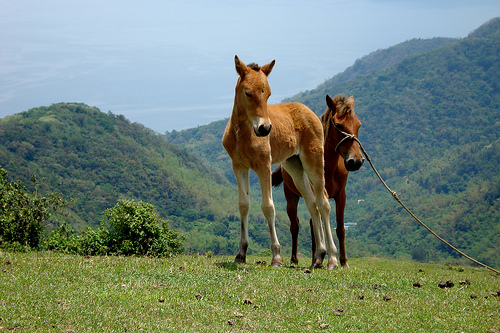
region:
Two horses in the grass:
[225, 53, 360, 270]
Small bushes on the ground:
[3, 169, 187, 254]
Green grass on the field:
[6, 246, 496, 331]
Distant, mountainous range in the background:
[20, 18, 496, 233]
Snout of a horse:
[250, 103, 274, 135]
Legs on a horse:
[224, 157, 340, 279]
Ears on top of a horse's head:
[235, 55, 274, 75]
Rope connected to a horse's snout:
[337, 125, 496, 277]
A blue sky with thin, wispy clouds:
[4, 3, 499, 113]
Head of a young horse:
[232, 53, 276, 137]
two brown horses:
[218, 52, 366, 272]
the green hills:
[3, 12, 498, 256]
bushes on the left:
[0, 159, 185, 261]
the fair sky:
[2, 2, 499, 132]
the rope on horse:
[337, 132, 494, 274]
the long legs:
[233, 157, 353, 272]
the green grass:
[4, 247, 499, 332]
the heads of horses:
[229, 44, 364, 171]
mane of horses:
[243, 59, 350, 116]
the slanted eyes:
[236, 87, 364, 132]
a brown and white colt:
[206, 65, 336, 267]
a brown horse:
[314, 85, 371, 242]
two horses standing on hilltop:
[194, 23, 389, 296]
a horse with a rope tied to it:
[319, 94, 479, 305]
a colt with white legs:
[227, 158, 319, 277]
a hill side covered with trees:
[373, 35, 488, 201]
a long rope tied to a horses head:
[339, 123, 497, 282]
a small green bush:
[60, 201, 202, 273]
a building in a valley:
[337, 210, 359, 245]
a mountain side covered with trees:
[0, 105, 179, 200]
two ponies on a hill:
[179, 38, 407, 295]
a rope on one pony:
[335, 129, 499, 284]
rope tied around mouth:
[328, 127, 390, 205]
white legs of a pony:
[221, 160, 390, 272]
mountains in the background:
[40, 35, 499, 255]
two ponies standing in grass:
[206, 57, 408, 304]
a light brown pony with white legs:
[207, 66, 355, 301]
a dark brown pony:
[268, 35, 401, 307]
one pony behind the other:
[219, 47, 411, 306]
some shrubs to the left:
[1, 162, 213, 275]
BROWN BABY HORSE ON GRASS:
[224, 59, 327, 259]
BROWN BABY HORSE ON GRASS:
[297, 87, 363, 196]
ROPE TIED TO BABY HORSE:
[350, 140, 417, 239]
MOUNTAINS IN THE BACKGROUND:
[2, 7, 482, 259]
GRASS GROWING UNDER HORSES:
[74, 249, 464, 331]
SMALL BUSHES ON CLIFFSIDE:
[0, 184, 170, 249]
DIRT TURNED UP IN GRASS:
[414, 270, 474, 292]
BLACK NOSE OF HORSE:
[336, 154, 363, 174]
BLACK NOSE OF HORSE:
[256, 121, 271, 140]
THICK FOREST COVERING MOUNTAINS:
[369, 83, 426, 120]